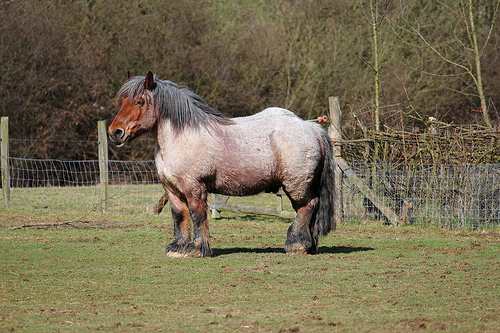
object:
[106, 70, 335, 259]
horse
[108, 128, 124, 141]
snout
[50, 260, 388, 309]
grass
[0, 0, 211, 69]
tree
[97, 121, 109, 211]
post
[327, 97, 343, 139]
post